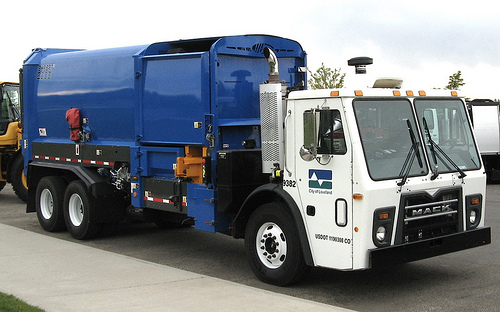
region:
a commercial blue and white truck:
[19, 33, 494, 288]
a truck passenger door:
[292, 94, 356, 270]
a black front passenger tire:
[243, 204, 305, 284]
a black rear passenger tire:
[61, 175, 102, 237]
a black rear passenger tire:
[33, 175, 60, 229]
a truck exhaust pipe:
[256, 45, 286, 178]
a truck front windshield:
[352, 96, 429, 182]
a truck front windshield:
[413, 93, 483, 175]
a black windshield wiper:
[390, 116, 423, 186]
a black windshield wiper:
[418, 112, 468, 180]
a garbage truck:
[14, 31, 499, 306]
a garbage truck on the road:
[11, 21, 497, 304]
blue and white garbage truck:
[5, 26, 476, 311]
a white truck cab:
[254, 38, 487, 260]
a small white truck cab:
[251, 30, 499, 275]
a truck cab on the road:
[248, 13, 497, 269]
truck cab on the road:
[242, 12, 499, 309]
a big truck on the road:
[8, 31, 455, 311]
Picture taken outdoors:
[14, 1, 433, 311]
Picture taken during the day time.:
[15, 11, 439, 296]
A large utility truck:
[26, 32, 439, 258]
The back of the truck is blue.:
[18, 45, 240, 181]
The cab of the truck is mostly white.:
[292, 67, 367, 242]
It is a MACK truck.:
[405, 187, 456, 219]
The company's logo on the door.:
[288, 160, 339, 191]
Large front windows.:
[341, 71, 496, 204]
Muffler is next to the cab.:
[256, 40, 304, 183]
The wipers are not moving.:
[383, 117, 483, 188]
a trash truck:
[9, 27, 486, 294]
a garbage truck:
[8, 26, 490, 306]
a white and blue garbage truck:
[15, 19, 487, 297]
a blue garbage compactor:
[26, 38, 307, 241]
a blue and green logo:
[299, 167, 344, 202]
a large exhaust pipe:
[249, 38, 297, 192]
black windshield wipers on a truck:
[392, 115, 477, 190]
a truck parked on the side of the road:
[5, 36, 498, 293]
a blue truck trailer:
[16, 8, 273, 226]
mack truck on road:
[18, 20, 474, 293]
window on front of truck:
[347, 85, 476, 182]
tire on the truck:
[243, 213, 302, 293]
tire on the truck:
[66, 188, 100, 247]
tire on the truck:
[33, 179, 58, 227]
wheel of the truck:
[254, 230, 284, 262]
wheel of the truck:
[69, 201, 84, 216]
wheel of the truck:
[41, 195, 56, 212]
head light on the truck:
[375, 226, 388, 243]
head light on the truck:
[461, 210, 487, 225]